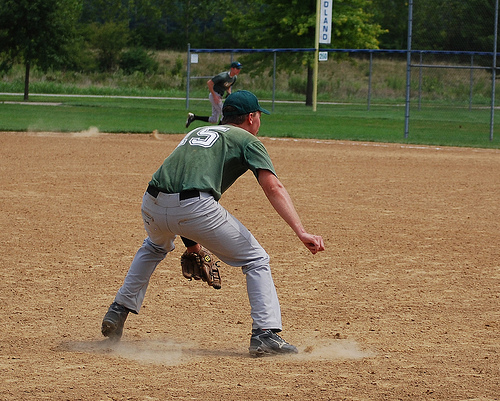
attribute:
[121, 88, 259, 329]
player — squatting down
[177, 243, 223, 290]
glove — brown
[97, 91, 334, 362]
man — wearing, playing baseball, holding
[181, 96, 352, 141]
hat — baseball, green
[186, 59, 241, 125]
man — playing baseball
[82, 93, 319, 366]
man — wearing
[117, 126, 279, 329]
baseball uniform — green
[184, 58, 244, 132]
player — running, baseball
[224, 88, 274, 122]
hat — green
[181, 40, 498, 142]
fence — metal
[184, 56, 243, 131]
man — running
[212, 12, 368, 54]
trees — leafy, green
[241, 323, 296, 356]
shoe — fielder's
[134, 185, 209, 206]
belt — black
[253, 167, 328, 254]
arm — fielder's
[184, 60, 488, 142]
fence — chainlink, grey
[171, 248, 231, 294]
baseball glove — brown